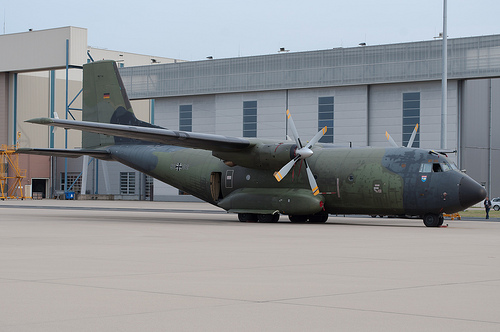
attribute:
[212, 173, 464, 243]
tires — black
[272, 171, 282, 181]
stripes — orange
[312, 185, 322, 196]
stripes — orange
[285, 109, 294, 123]
stripes — orange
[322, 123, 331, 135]
stripes — orange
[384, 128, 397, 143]
stripes — orange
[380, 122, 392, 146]
stripes — orange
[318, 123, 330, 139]
stripes — orange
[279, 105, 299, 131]
stripes — orange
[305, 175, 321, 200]
stripes — orange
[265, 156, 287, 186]
stripes — orange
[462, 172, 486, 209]
nose — black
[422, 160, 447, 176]
cockpit — window, open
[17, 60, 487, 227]
airplane — green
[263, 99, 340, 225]
propeller — grey, orange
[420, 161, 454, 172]
window — cockpit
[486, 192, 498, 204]
car — white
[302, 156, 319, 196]
blade — propeller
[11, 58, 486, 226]
plane — airforce, cargo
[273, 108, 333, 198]
stripes — orange